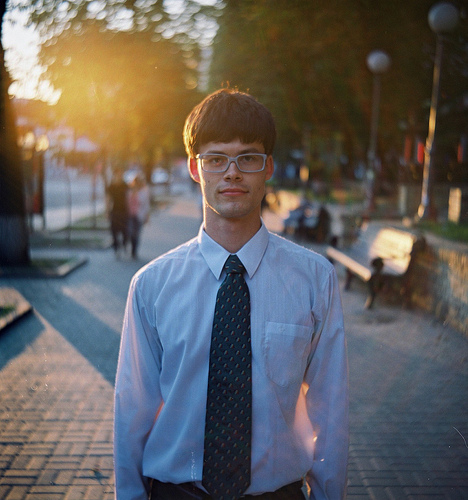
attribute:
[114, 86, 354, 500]
man — young, standing, dressed-up, smiling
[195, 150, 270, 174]
frames — plastic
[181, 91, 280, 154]
haircut — bowl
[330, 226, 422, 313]
bench — wooden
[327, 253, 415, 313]
legs — metal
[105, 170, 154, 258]
couple — walking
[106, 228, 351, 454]
shirt — white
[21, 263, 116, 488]
sidewalk — brick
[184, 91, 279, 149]
hair — short, brown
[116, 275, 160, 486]
sleeves — long